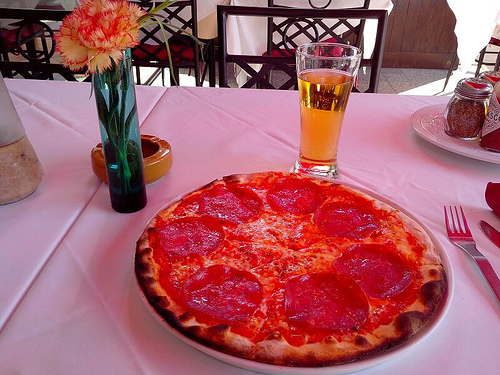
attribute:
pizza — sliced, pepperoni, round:
[133, 170, 447, 369]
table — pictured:
[0, 74, 499, 375]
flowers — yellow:
[54, 0, 148, 77]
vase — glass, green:
[90, 42, 149, 215]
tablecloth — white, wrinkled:
[0, 72, 499, 374]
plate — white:
[407, 94, 499, 166]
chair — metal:
[213, 2, 390, 98]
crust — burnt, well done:
[133, 169, 449, 370]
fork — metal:
[441, 201, 500, 301]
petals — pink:
[54, 0, 148, 77]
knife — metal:
[477, 217, 499, 248]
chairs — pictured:
[0, 1, 399, 95]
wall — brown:
[358, 0, 460, 72]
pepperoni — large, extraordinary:
[154, 176, 418, 334]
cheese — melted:
[160, 171, 424, 346]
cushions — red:
[123, 32, 347, 64]